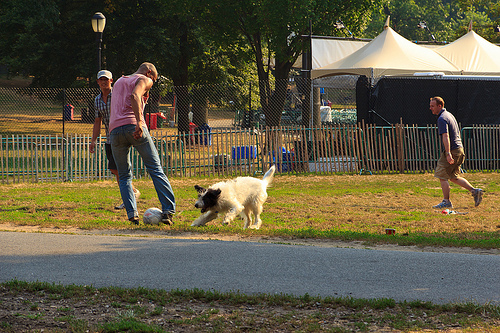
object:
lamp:
[90, 11, 107, 73]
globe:
[91, 12, 107, 33]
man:
[106, 61, 177, 226]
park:
[0, 0, 500, 333]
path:
[0, 227, 500, 310]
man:
[88, 69, 142, 211]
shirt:
[437, 107, 466, 153]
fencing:
[0, 116, 500, 185]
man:
[428, 96, 485, 212]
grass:
[0, 168, 500, 251]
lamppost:
[97, 32, 103, 74]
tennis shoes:
[431, 200, 454, 210]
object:
[268, 146, 295, 173]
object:
[232, 145, 258, 159]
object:
[210, 154, 230, 172]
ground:
[0, 73, 500, 254]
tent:
[310, 14, 500, 172]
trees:
[163, 0, 388, 155]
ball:
[142, 207, 163, 226]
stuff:
[318, 106, 358, 127]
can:
[64, 102, 75, 120]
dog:
[188, 164, 277, 230]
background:
[0, 0, 500, 137]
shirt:
[107, 73, 151, 136]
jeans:
[109, 123, 176, 220]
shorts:
[433, 147, 466, 182]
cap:
[97, 69, 114, 80]